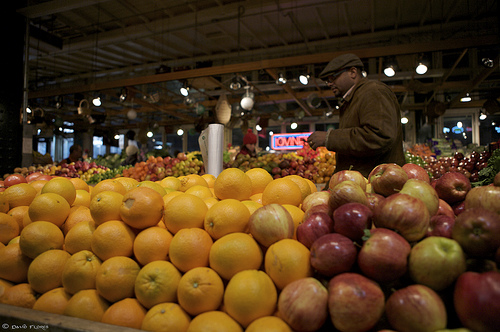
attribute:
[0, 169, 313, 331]
oranges — piled, piled up, stacked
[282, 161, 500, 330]
apples — piled, piled up, stacked, on right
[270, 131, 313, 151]
neon sign — present, on, red, blue, in background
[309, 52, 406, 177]
man — looking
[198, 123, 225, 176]
plastic bags — present, in roll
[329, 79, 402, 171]
jacket — brown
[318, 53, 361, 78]
hat — brown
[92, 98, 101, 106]
light — track light, in line, on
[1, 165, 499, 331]
fruits — on display, grouped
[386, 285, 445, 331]
apple — red, yellow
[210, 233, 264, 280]
orange — round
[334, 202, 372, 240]
apple — red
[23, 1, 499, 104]
ceiling — overhead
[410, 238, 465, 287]
apple — mostly green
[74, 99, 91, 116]
basket — hanging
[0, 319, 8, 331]
copyright symbol — present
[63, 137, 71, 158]
window — here